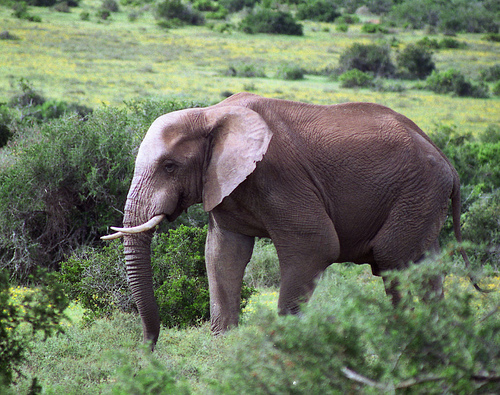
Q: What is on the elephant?
A: Skin.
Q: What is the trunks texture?
A: Wrinkled.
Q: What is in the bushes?
A: An elephant.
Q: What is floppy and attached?
A: Ear.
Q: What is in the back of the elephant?
A: Tail.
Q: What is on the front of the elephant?
A: Head.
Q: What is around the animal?
A: Bushed.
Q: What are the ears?
A: Floppy.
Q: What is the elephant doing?
A: Crossing a green field.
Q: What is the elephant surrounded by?
A: Green trees.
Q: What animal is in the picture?
A: An elephant.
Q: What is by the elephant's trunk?
A: A tusk.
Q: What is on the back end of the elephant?
A: A tail.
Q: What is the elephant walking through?
A: Grass and bushs.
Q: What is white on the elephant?
A: The tusks.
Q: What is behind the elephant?
A: Bushes.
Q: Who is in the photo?
A: Elephant.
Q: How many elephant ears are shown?
A: One.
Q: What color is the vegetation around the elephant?
A: Green.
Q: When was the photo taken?
A: Daytime.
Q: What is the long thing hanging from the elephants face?
A: Trunk.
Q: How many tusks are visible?
A: Two.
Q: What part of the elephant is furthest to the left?
A: Tusk.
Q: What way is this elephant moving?
A: Left.